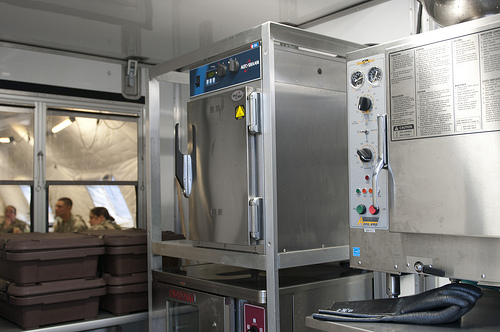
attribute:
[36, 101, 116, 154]
light — suspended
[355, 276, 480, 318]
gloves — rubber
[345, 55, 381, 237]
switch buttons — pictured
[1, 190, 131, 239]
people — trio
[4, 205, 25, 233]
person — alone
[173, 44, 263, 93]
label — brand 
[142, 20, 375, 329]
frame — metal equipment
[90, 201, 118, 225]
hair — black 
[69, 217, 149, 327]
gloves — black 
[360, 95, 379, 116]
knob — black, on oven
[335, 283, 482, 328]
gloves — long, black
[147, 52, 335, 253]
oven — commerical, kitchen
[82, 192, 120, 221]
hair — black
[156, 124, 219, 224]
handle — black, oven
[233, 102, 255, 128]
sticker — red, black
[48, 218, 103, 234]
uniform — green, army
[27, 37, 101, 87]
wall — white, painted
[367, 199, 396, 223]
button — round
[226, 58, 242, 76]
button — round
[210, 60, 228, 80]
knob — round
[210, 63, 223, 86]
knob — round